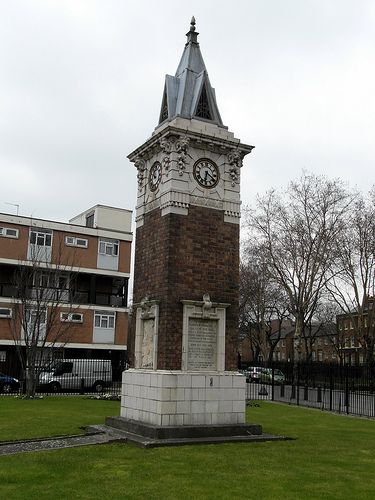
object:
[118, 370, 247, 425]
base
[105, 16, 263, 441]
tower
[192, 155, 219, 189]
clock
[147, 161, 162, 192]
clock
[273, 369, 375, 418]
fence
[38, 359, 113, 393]
van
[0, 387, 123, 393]
street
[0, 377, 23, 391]
car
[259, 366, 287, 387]
car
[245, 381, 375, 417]
street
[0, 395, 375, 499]
grass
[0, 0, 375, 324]
sky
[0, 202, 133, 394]
building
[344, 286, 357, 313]
branches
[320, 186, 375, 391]
tree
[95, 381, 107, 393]
wheel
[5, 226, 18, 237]
windows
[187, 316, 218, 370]
writing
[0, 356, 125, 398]
fence